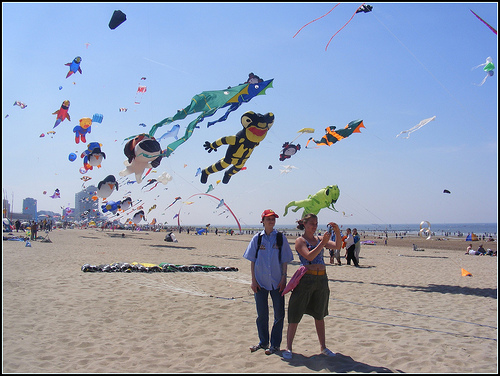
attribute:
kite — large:
[73, 243, 260, 289]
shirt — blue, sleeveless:
[297, 234, 325, 266]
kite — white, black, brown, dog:
[268, 90, 385, 185]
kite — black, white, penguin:
[89, 173, 118, 204]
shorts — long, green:
[284, 270, 331, 322]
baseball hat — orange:
[260, 210, 279, 219]